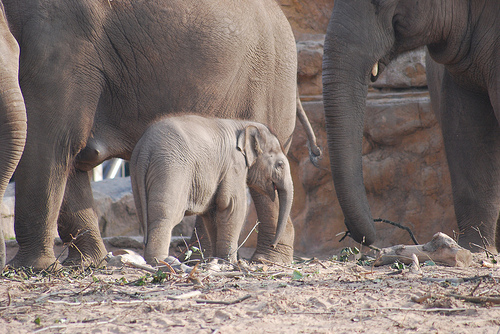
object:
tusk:
[360, 58, 381, 87]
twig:
[340, 215, 416, 242]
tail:
[133, 152, 158, 255]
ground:
[1, 237, 498, 333]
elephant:
[127, 115, 294, 270]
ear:
[230, 120, 271, 166]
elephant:
[320, 0, 499, 256]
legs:
[0, 91, 112, 271]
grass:
[0, 239, 498, 310]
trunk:
[314, 48, 388, 246]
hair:
[149, 110, 221, 123]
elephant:
[2, 2, 317, 272]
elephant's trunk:
[264, 170, 294, 254]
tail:
[293, 91, 324, 163]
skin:
[114, 5, 281, 111]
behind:
[132, 119, 172, 188]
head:
[325, 0, 491, 83]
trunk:
[121, 99, 299, 279]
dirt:
[166, 141, 231, 181]